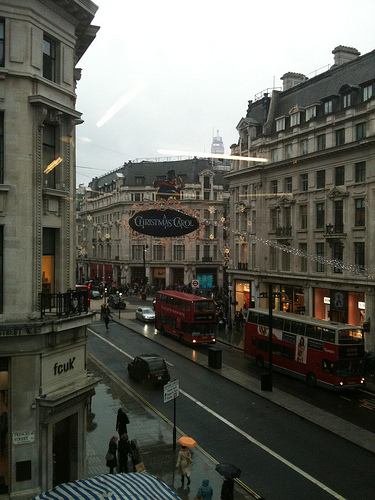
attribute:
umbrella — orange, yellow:
[178, 437, 195, 447]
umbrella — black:
[217, 463, 238, 477]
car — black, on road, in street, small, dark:
[128, 353, 168, 386]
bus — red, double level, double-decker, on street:
[156, 290, 214, 342]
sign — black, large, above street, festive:
[129, 208, 200, 237]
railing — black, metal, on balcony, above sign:
[39, 291, 89, 314]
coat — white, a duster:
[179, 450, 191, 479]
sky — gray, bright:
[78, 1, 368, 165]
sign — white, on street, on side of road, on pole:
[164, 381, 180, 402]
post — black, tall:
[171, 399, 177, 453]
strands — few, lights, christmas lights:
[194, 213, 369, 279]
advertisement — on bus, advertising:
[296, 336, 307, 365]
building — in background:
[80, 160, 229, 287]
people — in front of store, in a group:
[100, 282, 184, 292]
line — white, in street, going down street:
[89, 314, 346, 500]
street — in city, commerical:
[76, 273, 371, 500]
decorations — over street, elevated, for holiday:
[130, 167, 201, 242]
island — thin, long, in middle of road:
[109, 316, 370, 434]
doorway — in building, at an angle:
[48, 408, 84, 482]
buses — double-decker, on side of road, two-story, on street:
[153, 288, 366, 389]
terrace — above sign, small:
[36, 288, 98, 327]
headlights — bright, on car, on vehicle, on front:
[143, 316, 150, 321]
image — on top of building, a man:
[155, 170, 184, 202]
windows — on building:
[239, 89, 374, 275]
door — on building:
[54, 439, 72, 484]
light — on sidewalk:
[118, 292, 123, 322]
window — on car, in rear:
[147, 359, 165, 369]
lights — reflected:
[46, 73, 268, 173]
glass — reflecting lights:
[1, 1, 374, 499]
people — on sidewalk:
[104, 408, 238, 498]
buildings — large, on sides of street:
[2, 1, 372, 476]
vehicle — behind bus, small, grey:
[136, 306, 152, 322]